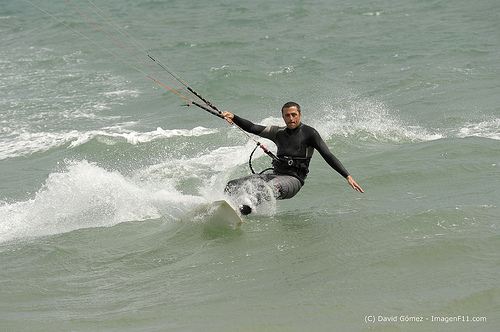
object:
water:
[0, 1, 499, 331]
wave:
[0, 107, 72, 147]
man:
[216, 102, 365, 216]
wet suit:
[221, 112, 349, 215]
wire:
[22, 0, 224, 119]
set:
[86, 0, 281, 162]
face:
[280, 106, 300, 129]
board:
[201, 199, 242, 231]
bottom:
[221, 172, 304, 216]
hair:
[280, 102, 302, 118]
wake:
[15, 161, 261, 218]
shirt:
[231, 113, 352, 182]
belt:
[271, 155, 309, 176]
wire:
[221, 116, 282, 162]